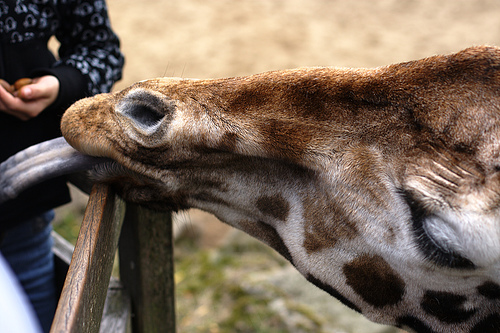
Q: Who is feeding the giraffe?
A: Girl.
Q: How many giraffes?
A: One.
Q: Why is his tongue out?
A: Eating.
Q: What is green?
A: Grass.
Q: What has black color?
A: Shirt.